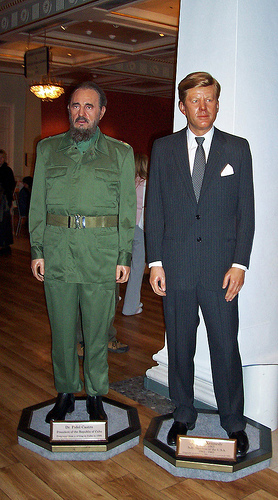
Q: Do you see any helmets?
A: No, there are no helmets.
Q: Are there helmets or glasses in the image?
A: No, there are no helmets or glasses.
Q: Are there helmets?
A: No, there are no helmets.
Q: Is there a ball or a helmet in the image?
A: No, there are no helmets or balls.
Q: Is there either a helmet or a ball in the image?
A: No, there are no helmets or balls.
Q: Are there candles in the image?
A: No, there are no candles.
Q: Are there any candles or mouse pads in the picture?
A: No, there are no candles or mouse pads.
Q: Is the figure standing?
A: Yes, the figure is standing.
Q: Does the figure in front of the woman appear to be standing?
A: Yes, the figure is standing.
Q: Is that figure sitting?
A: No, the figure is standing.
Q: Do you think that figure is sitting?
A: No, the figure is standing.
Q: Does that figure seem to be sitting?
A: No, the figure is standing.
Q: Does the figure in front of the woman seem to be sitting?
A: No, the figure is standing.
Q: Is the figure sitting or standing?
A: The figure is standing.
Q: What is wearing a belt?
A: The figure is wearing a belt.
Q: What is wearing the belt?
A: The figure is wearing a belt.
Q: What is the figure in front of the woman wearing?
A: The figure is wearing a belt.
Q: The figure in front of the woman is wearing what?
A: The figure is wearing a belt.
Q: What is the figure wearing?
A: The figure is wearing a belt.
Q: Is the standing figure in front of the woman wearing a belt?
A: Yes, the figure is wearing a belt.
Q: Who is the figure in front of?
A: The figure is in front of the woman.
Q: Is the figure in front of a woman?
A: Yes, the figure is in front of a woman.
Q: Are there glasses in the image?
A: No, there are no glasses.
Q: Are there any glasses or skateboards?
A: No, there are no glasses or skateboards.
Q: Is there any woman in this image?
A: Yes, there is a woman.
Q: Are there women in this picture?
A: Yes, there is a woman.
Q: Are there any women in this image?
A: Yes, there is a woman.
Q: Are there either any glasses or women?
A: Yes, there is a woman.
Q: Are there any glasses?
A: No, there are no glasses.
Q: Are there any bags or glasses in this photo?
A: No, there are no glasses or bags.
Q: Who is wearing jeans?
A: The woman is wearing jeans.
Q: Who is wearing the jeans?
A: The woman is wearing jeans.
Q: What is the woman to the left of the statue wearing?
A: The woman is wearing jeans.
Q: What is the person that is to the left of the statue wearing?
A: The woman is wearing jeans.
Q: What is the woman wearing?
A: The woman is wearing jeans.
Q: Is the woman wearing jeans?
A: Yes, the woman is wearing jeans.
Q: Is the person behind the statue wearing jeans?
A: Yes, the woman is wearing jeans.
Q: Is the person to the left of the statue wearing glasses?
A: No, the woman is wearing jeans.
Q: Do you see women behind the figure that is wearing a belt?
A: Yes, there is a woman behind the figure.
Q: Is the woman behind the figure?
A: Yes, the woman is behind the figure.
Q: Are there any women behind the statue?
A: Yes, there is a woman behind the statue.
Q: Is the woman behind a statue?
A: Yes, the woman is behind a statue.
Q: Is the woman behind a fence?
A: No, the woman is behind a statue.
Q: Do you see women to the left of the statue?
A: Yes, there is a woman to the left of the statue.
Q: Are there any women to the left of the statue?
A: Yes, there is a woman to the left of the statue.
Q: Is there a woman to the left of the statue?
A: Yes, there is a woman to the left of the statue.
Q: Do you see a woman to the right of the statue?
A: No, the woman is to the left of the statue.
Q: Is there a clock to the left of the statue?
A: No, there is a woman to the left of the statue.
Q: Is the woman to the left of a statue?
A: Yes, the woman is to the left of a statue.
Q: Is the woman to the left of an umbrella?
A: No, the woman is to the left of a statue.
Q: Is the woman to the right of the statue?
A: No, the woman is to the left of the statue.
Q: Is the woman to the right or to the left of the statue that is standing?
A: The woman is to the left of the statue.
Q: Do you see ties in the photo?
A: Yes, there is a tie.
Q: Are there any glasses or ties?
A: Yes, there is a tie.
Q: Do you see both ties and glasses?
A: No, there is a tie but no glasses.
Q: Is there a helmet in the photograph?
A: No, there are no helmets.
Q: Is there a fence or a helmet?
A: No, there are no helmets or fences.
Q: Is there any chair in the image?
A: No, there are no chairs.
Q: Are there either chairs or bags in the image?
A: No, there are no chairs or bags.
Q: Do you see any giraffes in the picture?
A: No, there are no giraffes.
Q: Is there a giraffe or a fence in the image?
A: No, there are no giraffes or fences.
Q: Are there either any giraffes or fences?
A: No, there are no giraffes or fences.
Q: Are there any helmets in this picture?
A: No, there are no helmets.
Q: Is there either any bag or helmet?
A: No, there are no helmets or bags.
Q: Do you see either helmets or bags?
A: No, there are no helmets or bags.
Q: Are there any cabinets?
A: No, there are no cabinets.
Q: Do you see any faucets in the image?
A: No, there are no faucets.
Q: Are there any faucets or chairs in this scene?
A: No, there are no faucets or chairs.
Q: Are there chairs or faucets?
A: No, there are no faucets or chairs.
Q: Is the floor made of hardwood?
A: Yes, the floor is made of hardwood.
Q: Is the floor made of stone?
A: No, the floor is made of hardwood.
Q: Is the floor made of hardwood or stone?
A: The floor is made of hardwood.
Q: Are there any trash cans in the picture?
A: No, there are no trash cans.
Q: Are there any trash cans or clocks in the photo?
A: No, there are no trash cans or clocks.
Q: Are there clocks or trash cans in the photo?
A: No, there are no trash cans or clocks.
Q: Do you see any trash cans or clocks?
A: No, there are no trash cans or clocks.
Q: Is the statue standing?
A: Yes, the statue is standing.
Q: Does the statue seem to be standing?
A: Yes, the statue is standing.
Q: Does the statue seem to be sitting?
A: No, the statue is standing.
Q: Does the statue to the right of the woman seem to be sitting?
A: No, the statue is standing.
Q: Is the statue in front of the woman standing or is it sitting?
A: The statue is standing.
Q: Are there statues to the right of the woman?
A: Yes, there is a statue to the right of the woman.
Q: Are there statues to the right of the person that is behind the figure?
A: Yes, there is a statue to the right of the woman.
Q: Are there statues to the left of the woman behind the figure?
A: No, the statue is to the right of the woman.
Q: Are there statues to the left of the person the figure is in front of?
A: No, the statue is to the right of the woman.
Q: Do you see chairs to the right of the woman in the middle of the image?
A: No, there is a statue to the right of the woman.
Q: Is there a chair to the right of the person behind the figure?
A: No, there is a statue to the right of the woman.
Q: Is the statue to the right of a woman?
A: Yes, the statue is to the right of a woman.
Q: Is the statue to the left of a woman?
A: No, the statue is to the right of a woman.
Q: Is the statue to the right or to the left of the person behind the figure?
A: The statue is to the right of the woman.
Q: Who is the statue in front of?
A: The statue is in front of the woman.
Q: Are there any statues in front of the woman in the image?
A: Yes, there is a statue in front of the woman.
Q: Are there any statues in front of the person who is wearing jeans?
A: Yes, there is a statue in front of the woman.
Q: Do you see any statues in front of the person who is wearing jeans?
A: Yes, there is a statue in front of the woman.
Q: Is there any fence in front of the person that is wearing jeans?
A: No, there is a statue in front of the woman.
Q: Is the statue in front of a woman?
A: Yes, the statue is in front of a woman.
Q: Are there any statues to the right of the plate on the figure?
A: Yes, there is a statue to the right of the plate.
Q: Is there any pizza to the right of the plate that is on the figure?
A: No, there is a statue to the right of the plate.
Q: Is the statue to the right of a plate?
A: Yes, the statue is to the right of a plate.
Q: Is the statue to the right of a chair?
A: No, the statue is to the right of a plate.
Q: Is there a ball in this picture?
A: No, there are no balls.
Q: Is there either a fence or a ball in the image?
A: No, there are no balls or fences.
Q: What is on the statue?
A: The shoe is on the statue.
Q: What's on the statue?
A: The shoe is on the statue.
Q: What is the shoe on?
A: The shoe is on the statue.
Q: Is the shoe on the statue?
A: Yes, the shoe is on the statue.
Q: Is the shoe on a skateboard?
A: No, the shoe is on the statue.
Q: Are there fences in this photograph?
A: No, there are no fences.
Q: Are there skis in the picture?
A: No, there are no skis.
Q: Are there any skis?
A: No, there are no skis.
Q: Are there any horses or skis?
A: No, there are no skis or horses.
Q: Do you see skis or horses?
A: No, there are no skis or horses.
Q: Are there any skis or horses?
A: No, there are no skis or horses.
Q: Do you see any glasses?
A: No, there are no glasses.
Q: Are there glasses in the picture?
A: No, there are no glasses.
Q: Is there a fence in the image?
A: No, there are no fences.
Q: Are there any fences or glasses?
A: No, there are no fences or glasses.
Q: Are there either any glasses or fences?
A: No, there are no fences or glasses.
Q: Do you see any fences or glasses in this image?
A: No, there are no fences or glasses.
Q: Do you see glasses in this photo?
A: No, there are no glasses.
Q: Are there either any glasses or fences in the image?
A: No, there are no glasses or fences.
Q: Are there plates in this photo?
A: Yes, there is a plate.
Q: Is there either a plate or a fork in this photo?
A: Yes, there is a plate.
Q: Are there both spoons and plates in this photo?
A: No, there is a plate but no spoons.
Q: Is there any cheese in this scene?
A: No, there is no cheese.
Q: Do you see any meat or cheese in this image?
A: No, there are no cheese or meat.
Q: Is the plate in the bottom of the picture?
A: Yes, the plate is in the bottom of the image.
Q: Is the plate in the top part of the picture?
A: No, the plate is in the bottom of the image.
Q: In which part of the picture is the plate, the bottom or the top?
A: The plate is in the bottom of the image.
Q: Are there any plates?
A: Yes, there is a plate.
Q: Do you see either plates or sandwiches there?
A: Yes, there is a plate.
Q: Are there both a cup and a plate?
A: No, there is a plate but no cups.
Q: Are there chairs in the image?
A: No, there are no chairs.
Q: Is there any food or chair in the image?
A: No, there are no chairs or food.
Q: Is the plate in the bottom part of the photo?
A: Yes, the plate is in the bottom of the image.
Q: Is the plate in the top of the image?
A: No, the plate is in the bottom of the image.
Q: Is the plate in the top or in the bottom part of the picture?
A: The plate is in the bottom of the image.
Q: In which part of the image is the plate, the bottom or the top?
A: The plate is in the bottom of the image.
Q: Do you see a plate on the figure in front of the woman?
A: Yes, there is a plate on the figure.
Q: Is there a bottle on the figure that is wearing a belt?
A: No, there is a plate on the figure.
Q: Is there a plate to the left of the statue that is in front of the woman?
A: Yes, there is a plate to the left of the statue.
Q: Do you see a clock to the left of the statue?
A: No, there is a plate to the left of the statue.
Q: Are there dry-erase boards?
A: No, there are no dry-erase boards.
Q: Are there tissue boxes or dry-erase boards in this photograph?
A: No, there are no dry-erase boards or tissue boxes.